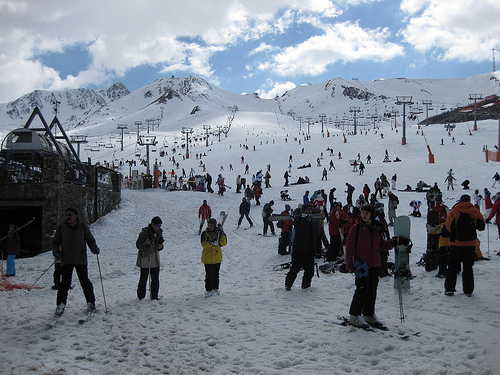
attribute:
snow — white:
[0, 80, 496, 371]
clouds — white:
[323, 21, 407, 74]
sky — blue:
[253, 1, 498, 87]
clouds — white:
[282, 28, 396, 74]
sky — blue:
[22, 1, 499, 89]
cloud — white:
[2, 2, 244, 47]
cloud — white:
[87, 39, 228, 83]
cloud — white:
[0, 56, 64, 107]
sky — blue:
[380, 29, 420, 70]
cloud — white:
[255, 18, 405, 78]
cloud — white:
[395, 0, 499, 64]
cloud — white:
[1, 0, 343, 102]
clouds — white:
[2, 1, 499, 103]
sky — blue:
[1, 0, 496, 107]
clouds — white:
[416, 6, 496, 56]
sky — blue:
[4, 4, 498, 85]